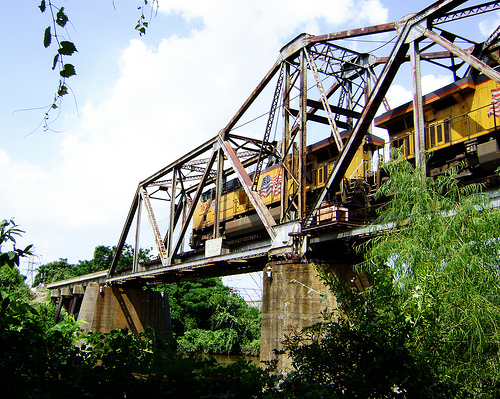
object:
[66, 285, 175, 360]
stone column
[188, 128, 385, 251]
car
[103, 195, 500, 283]
tracks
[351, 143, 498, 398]
tree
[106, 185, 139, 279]
bar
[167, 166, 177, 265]
bar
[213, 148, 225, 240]
bar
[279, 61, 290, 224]
bar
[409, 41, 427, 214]
bar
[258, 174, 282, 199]
flag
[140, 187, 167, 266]
bar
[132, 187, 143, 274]
bar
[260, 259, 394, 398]
pillar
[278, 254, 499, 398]
trees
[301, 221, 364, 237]
platform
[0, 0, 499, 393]
bridge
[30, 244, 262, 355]
wooded area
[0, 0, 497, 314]
sky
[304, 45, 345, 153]
metal bar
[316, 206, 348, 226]
guard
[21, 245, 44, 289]
electric tower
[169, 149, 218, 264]
bar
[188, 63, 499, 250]
train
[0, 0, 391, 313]
cloud